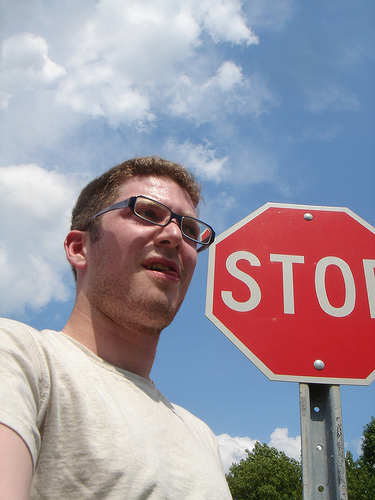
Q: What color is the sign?
A: Red.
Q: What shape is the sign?
A: Octagon.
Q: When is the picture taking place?
A: Daytime.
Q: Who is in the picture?
A: A man.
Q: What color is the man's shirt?
A: White.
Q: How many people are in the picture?
A: One.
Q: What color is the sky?
A: Blue.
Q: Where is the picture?
A: At an intersection.